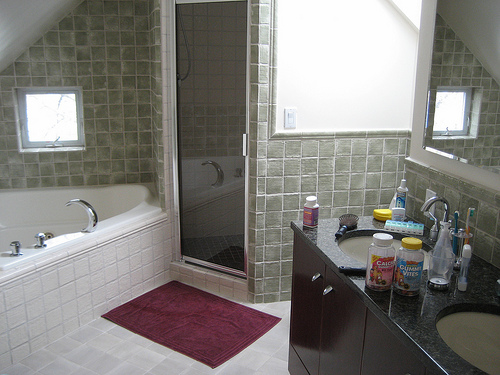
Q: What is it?
A: Bathroom.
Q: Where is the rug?
A: On the floor.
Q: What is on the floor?
A: Tile.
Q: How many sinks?
A: 2.